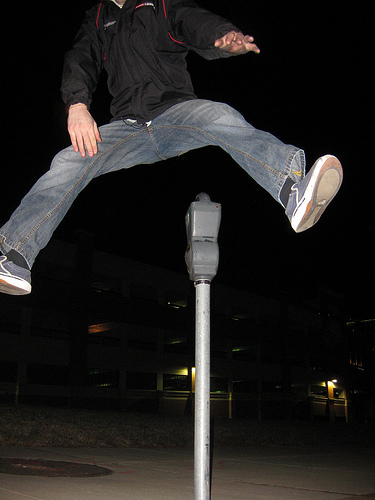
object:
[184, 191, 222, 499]
meter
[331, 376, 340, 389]
lights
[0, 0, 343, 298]
person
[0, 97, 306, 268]
pants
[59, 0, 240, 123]
jacket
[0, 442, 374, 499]
road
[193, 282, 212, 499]
pole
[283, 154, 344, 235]
shoe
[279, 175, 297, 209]
socks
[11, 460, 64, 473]
graffiti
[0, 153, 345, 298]
shoes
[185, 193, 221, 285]
meter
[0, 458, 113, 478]
manhole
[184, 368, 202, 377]
porchlight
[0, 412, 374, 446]
grass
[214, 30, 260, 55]
hand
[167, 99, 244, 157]
thigh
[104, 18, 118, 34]
lettering